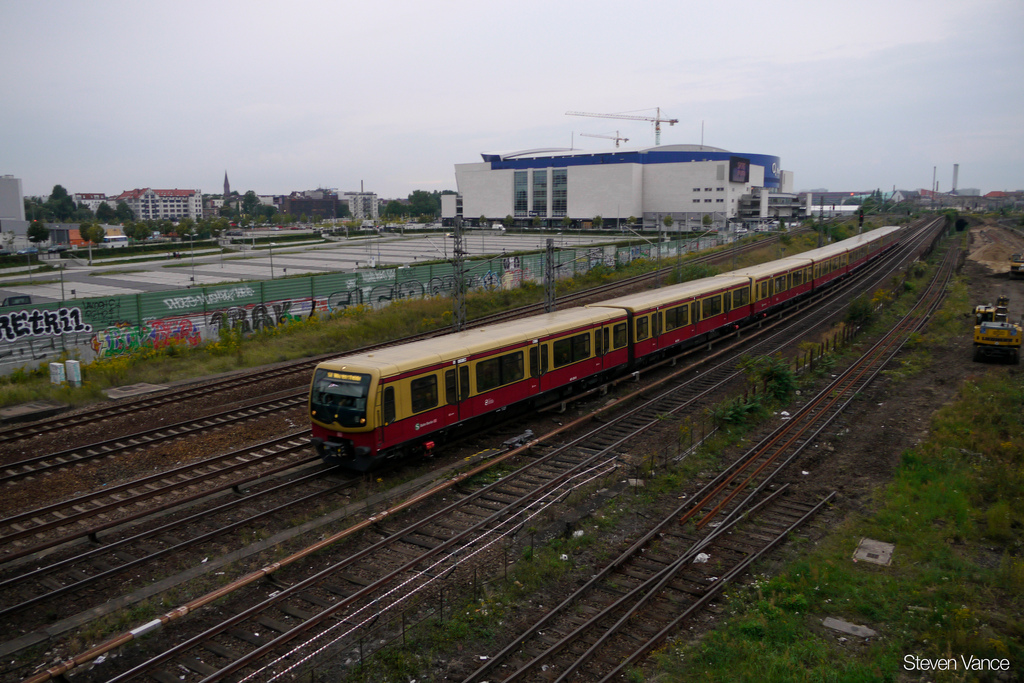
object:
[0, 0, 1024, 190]
cloud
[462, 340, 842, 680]
tracks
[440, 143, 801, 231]
building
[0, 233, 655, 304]
parking lot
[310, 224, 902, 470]
train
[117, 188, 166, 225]
building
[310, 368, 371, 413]
window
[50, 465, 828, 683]
tracks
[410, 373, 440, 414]
window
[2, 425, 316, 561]
tracks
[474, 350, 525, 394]
window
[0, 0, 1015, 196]
sky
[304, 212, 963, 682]
vegetation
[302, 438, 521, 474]
bottom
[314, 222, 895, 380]
top